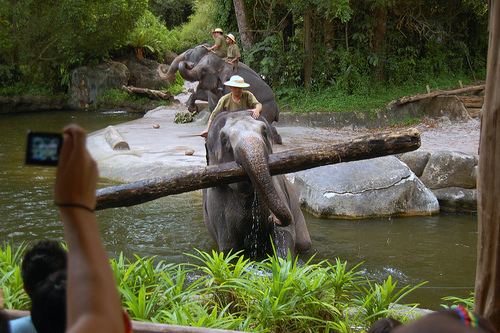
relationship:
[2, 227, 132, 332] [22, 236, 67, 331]
children have hair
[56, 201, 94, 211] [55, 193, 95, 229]
strap on wrist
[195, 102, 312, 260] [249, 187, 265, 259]
elephant has water dripping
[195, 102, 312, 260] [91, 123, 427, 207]
elephant carrying log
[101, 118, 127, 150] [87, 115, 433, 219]
log in cement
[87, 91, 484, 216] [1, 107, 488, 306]
rock near water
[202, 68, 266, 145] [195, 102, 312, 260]
rider on elephant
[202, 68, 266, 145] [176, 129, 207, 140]
rider holding stick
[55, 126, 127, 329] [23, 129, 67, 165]
arm holding up camera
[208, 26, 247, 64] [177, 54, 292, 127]
people riding elephants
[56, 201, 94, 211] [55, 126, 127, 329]
strap on arm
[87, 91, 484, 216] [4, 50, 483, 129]
rock on bank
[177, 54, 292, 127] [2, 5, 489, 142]
elephants in background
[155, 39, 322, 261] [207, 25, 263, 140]
elephants with riders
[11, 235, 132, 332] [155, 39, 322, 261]
children watching elephants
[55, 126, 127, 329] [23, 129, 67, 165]
arm using camera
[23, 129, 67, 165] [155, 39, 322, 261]
camera recording elephants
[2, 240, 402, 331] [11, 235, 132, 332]
plants in front of children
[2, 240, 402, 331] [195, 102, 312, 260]
plants in front of elephant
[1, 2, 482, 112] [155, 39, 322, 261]
vegetation behind elephants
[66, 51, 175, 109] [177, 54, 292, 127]
boulders next to elephants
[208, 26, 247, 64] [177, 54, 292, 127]
people on elephants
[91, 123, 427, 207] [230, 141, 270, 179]
log in mouth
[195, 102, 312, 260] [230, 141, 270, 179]
elephant has mouth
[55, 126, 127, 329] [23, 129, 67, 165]
arm holding camera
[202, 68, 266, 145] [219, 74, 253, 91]
rider wearing hat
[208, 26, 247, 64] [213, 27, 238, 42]
people wearing hats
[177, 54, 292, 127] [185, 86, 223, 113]
elephants holding up legs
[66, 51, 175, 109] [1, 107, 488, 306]
boulders by water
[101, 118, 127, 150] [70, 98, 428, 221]
log on ground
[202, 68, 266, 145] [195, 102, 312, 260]
rider riding elephant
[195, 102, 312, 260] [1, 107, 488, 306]
elephant crossing water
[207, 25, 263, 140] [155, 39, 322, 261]
riders riding elephants